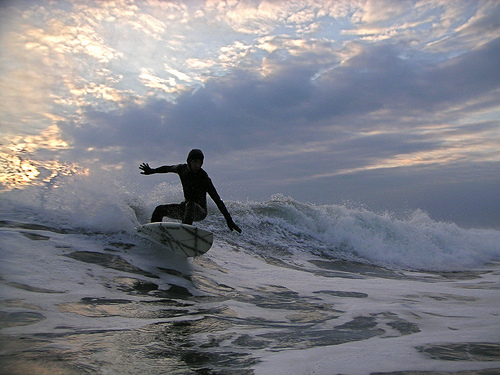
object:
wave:
[0, 172, 500, 270]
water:
[0, 162, 500, 375]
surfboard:
[136, 221, 216, 258]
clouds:
[0, 0, 500, 232]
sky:
[0, 0, 500, 234]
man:
[137, 147, 245, 234]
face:
[190, 156, 204, 172]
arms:
[207, 182, 232, 222]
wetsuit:
[151, 165, 231, 225]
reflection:
[123, 228, 245, 374]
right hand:
[138, 161, 153, 176]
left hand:
[226, 220, 243, 234]